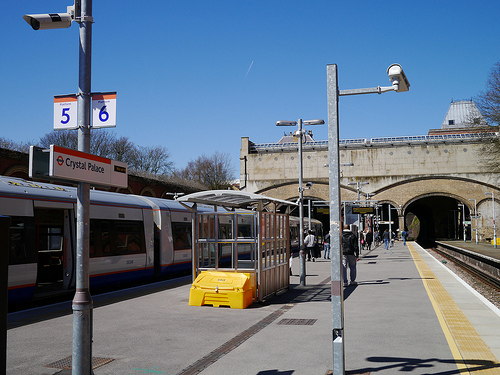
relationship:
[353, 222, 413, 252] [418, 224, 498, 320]
people walking alongside tracks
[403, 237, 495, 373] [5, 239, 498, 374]
line on ground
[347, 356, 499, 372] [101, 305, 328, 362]
shadow on ground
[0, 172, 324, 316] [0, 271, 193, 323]
train on tracks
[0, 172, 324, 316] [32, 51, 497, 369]
train at station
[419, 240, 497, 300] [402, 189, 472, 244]
tracks inside tunnel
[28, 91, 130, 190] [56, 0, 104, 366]
sign on pole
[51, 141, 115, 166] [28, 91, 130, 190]
stripe on sign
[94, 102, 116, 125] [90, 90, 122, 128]
blue number on background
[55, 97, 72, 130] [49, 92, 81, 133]
blue number on background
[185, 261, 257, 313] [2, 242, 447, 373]
yellow box on concrete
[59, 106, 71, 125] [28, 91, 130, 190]
number 5 on sign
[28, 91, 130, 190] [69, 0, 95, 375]
sign on pole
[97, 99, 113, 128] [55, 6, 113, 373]
6 on pole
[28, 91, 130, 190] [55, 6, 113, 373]
sign on pole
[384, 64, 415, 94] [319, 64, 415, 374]
light on pole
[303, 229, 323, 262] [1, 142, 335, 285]
person looking at train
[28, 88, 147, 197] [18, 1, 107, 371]
sign on pole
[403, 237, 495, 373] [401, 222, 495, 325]
line next to train track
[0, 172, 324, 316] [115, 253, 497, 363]
train at station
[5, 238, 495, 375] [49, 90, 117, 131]
platform shows platform number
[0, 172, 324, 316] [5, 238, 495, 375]
train at platform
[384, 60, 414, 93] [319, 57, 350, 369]
security camera attached to a pole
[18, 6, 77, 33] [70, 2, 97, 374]
security camera attached to a pole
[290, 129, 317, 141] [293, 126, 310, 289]
security camera attached to a pole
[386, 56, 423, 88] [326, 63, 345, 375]
camera on pole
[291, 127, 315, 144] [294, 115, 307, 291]
camera attached to a pole